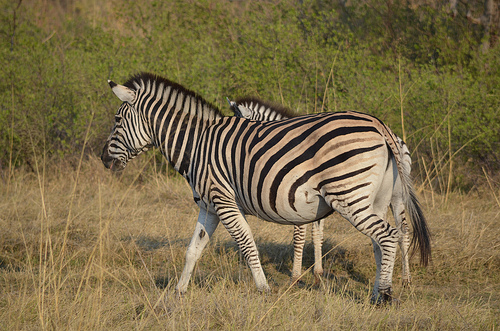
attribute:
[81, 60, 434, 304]
zebra — adult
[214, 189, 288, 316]
leg — zebra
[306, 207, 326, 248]
ground — black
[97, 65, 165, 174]
head — black and white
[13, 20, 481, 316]
scene — sunny, daytime, outdoor, field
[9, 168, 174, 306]
grass — tall, brown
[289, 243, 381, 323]
grass — tall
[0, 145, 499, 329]
grass — dry, green 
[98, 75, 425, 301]
animal — black, white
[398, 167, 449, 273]
tail — black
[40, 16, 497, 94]
bushes — green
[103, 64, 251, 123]
mohawk — black and white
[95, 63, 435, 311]
body — black, white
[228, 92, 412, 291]
animal — white